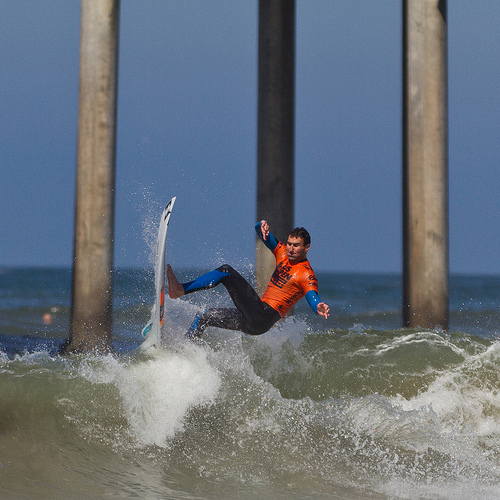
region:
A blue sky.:
[0, 2, 499, 268]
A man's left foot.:
[166, 262, 185, 301]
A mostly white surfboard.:
[152, 197, 174, 351]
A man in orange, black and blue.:
[165, 219, 328, 354]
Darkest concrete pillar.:
[253, 0, 296, 317]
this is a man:
[70, 145, 394, 397]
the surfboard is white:
[135, 180, 194, 396]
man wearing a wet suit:
[162, 169, 334, 366]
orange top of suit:
[255, 240, 334, 331]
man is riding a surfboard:
[28, 100, 494, 497]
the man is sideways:
[57, 148, 356, 370]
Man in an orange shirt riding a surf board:
[146, 193, 331, 347]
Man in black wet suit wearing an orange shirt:
[167, 220, 330, 340]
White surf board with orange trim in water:
[140, 191, 172, 364]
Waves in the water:
[1, 345, 498, 497]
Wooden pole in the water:
[396, 1, 453, 336]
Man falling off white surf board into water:
[140, 195, 334, 370]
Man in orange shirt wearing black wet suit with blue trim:
[163, 215, 332, 350]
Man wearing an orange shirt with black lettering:
[260, 213, 330, 317]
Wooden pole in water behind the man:
[252, 3, 299, 325]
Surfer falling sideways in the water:
[142, 196, 328, 357]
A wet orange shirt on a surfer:
[250, 243, 318, 313]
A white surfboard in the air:
[145, 190, 177, 355]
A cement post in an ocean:
[72, 1, 116, 360]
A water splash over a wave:
[116, 185, 163, 337]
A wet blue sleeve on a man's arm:
[302, 288, 319, 308]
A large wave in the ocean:
[12, 332, 494, 494]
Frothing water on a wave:
[130, 354, 243, 432]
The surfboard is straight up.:
[148, 187, 199, 358]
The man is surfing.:
[156, 201, 336, 353]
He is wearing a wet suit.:
[158, 223, 338, 343]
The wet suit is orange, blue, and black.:
[169, 216, 330, 346]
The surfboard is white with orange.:
[138, 198, 185, 373]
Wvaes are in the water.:
[18, 343, 490, 453]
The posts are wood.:
[399, 5, 458, 328]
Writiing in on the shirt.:
[265, 260, 302, 300]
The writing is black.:
[266, 259, 293, 302]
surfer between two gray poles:
[67, 3, 452, 360]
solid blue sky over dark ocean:
[5, 7, 493, 305]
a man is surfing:
[165, 210, 337, 342]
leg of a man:
[184, 267, 257, 312]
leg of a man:
[188, 306, 240, 337]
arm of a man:
[301, 276, 332, 326]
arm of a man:
[255, 220, 282, 252]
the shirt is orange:
[270, 244, 315, 311]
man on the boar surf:
[151, 198, 328, 359]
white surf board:
[150, 189, 175, 349]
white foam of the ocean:
[106, 345, 238, 427]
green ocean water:
[22, 395, 137, 473]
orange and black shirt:
[273, 255, 307, 308]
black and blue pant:
[187, 273, 270, 333]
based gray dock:
[82, 14, 116, 350]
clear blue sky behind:
[129, 19, 245, 159]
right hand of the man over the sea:
[250, 214, 274, 247]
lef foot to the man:
[167, 262, 187, 300]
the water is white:
[141, 367, 208, 421]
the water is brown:
[43, 428, 95, 475]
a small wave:
[352, 388, 421, 439]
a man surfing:
[193, 206, 348, 343]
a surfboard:
[150, 218, 183, 340]